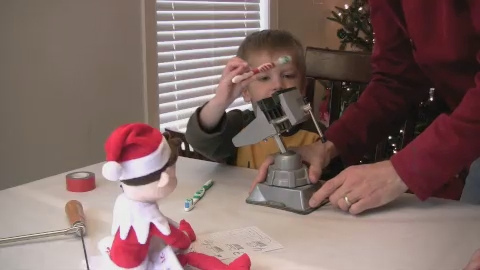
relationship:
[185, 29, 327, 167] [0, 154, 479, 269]
boy behind table